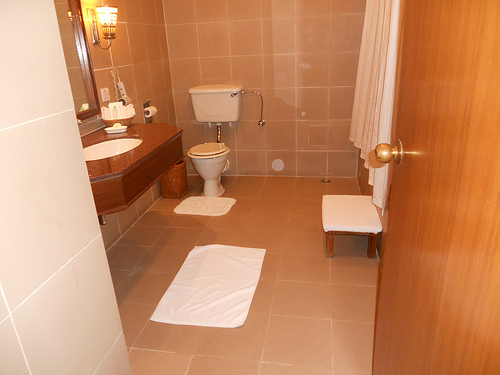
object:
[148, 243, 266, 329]
towel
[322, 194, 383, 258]
stool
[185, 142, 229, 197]
toilet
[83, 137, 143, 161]
sink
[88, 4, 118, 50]
fixture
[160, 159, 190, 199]
trash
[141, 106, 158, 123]
paper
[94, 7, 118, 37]
light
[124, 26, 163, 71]
wall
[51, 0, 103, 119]
mirror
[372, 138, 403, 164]
knob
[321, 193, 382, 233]
cover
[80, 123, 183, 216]
counter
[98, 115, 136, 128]
basket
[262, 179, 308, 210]
tile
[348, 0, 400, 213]
curtain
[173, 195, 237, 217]
mat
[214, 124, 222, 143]
pipe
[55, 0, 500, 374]
bathroom